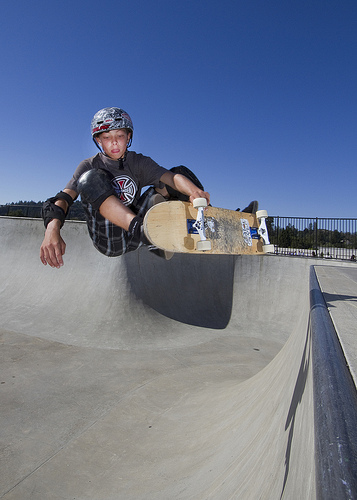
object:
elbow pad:
[41, 190, 74, 227]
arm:
[39, 158, 91, 228]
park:
[0, 197, 355, 496]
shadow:
[133, 252, 237, 336]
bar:
[308, 262, 355, 496]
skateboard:
[141, 200, 276, 256]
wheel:
[193, 197, 209, 207]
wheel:
[198, 239, 210, 252]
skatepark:
[0, 224, 357, 500]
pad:
[65, 165, 113, 213]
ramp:
[228, 262, 355, 497]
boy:
[39, 105, 213, 299]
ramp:
[1, 214, 82, 324]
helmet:
[89, 106, 133, 146]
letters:
[90, 123, 109, 135]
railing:
[274, 214, 356, 260]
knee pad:
[165, 161, 207, 199]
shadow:
[277, 286, 357, 498]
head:
[90, 106, 132, 162]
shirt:
[65, 148, 164, 215]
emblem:
[111, 171, 138, 207]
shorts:
[83, 183, 164, 258]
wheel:
[254, 209, 269, 219]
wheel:
[263, 244, 275, 254]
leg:
[76, 170, 146, 239]